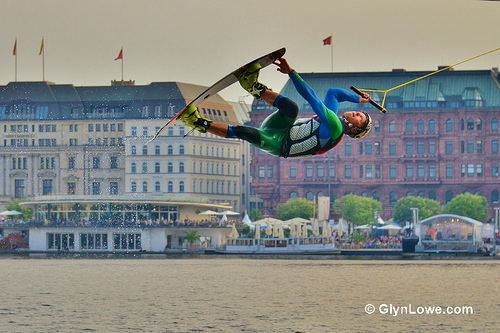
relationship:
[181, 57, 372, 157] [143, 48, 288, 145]
man on ski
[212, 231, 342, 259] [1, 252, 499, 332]
boat on water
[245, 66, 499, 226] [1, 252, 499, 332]
building in water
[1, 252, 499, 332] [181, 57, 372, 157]
water below man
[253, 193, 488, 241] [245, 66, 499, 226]
trees in front of building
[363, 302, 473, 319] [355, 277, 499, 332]
trademark in corner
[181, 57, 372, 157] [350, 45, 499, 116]
man holding rope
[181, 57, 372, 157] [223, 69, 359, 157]
man wearing wetsuit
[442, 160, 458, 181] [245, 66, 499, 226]
window on building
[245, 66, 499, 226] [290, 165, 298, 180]
building has a window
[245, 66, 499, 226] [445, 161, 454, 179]
building has a window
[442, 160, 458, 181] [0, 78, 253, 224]
window on building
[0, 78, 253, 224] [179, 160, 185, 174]
building has a window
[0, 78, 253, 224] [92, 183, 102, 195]
building has a window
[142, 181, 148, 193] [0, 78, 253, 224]
window on building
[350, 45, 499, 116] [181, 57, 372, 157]
rope held by man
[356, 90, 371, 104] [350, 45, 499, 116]
hand holding rope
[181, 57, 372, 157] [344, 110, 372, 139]
man wearing helmet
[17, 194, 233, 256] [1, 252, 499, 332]
covered area next to water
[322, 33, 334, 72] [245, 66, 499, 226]
flag on building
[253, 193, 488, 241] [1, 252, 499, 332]
trees near water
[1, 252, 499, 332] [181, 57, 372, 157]
water beneath man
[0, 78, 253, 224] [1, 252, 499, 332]
building near water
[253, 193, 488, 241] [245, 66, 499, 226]
trees near building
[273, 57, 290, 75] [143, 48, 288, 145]
left hand touching ski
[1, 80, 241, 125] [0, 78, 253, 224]
roof on building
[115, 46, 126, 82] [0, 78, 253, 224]
flag on building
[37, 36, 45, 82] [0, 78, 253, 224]
flag on building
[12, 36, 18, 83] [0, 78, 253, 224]
flag on building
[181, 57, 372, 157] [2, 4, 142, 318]
man in air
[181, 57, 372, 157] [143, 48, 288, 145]
man with ski